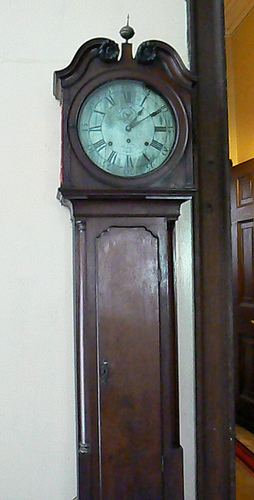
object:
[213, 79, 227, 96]
ground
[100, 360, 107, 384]
handle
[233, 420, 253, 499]
floor pattern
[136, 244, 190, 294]
reflection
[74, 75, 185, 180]
clock face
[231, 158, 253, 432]
door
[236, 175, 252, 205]
bevels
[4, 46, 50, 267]
wall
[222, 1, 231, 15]
giraffe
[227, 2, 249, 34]
border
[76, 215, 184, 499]
door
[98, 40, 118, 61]
decoration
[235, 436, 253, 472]
carpet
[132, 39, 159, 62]
rosettes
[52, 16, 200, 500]
clock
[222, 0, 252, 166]
wall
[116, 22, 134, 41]
decoration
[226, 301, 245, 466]
mirror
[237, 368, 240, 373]
people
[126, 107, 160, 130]
hands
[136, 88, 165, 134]
1:10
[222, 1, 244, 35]
trimming